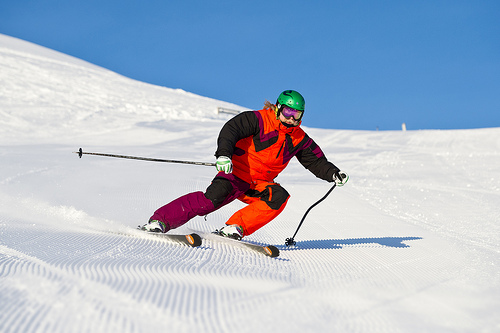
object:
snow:
[388, 205, 461, 280]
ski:
[135, 220, 203, 248]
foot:
[216, 225, 242, 237]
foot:
[140, 219, 167, 232]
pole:
[72, 147, 233, 171]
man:
[138, 89, 348, 257]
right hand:
[214, 155, 233, 174]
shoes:
[143, 219, 244, 238]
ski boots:
[136, 220, 202, 244]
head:
[275, 90, 307, 128]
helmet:
[277, 89, 306, 112]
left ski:
[186, 223, 279, 257]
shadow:
[235, 236, 425, 262]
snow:
[5, 258, 493, 329]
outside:
[72, 83, 141, 265]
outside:
[253, 277, 475, 324]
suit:
[149, 89, 346, 236]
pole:
[285, 174, 346, 245]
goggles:
[279, 105, 303, 121]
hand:
[332, 171, 349, 187]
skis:
[188, 225, 281, 258]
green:
[289, 97, 296, 104]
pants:
[148, 170, 292, 236]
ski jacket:
[213, 101, 343, 186]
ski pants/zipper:
[267, 185, 273, 202]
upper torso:
[214, 82, 350, 183]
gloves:
[333, 170, 350, 187]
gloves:
[214, 156, 235, 175]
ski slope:
[0, 36, 500, 333]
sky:
[0, 0, 500, 132]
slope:
[0, 82, 499, 330]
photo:
[0, 10, 500, 333]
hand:
[215, 154, 234, 174]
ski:
[208, 221, 280, 260]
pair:
[136, 211, 281, 257]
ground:
[109, 247, 366, 307]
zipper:
[203, 190, 242, 221]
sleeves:
[214, 111, 260, 159]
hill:
[0, 49, 226, 123]